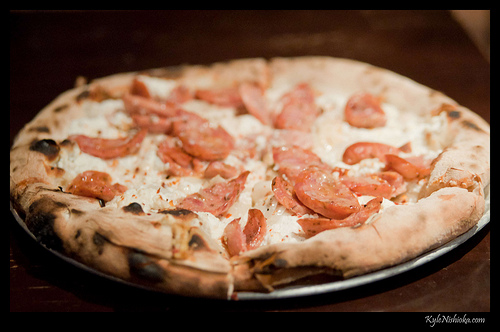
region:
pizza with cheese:
[32, 73, 496, 298]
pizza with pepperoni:
[29, 56, 486, 276]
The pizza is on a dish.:
[16, 60, 471, 297]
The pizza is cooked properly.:
[5, 20, 471, 300]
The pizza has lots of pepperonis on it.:
[25, 55, 476, 301]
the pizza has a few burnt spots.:
[15, 27, 481, 294]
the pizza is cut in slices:
[28, 55, 468, 305]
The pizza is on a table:
[10, 25, 476, 312]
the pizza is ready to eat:
[8, 50, 484, 290]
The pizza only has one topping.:
[15, 42, 402, 317]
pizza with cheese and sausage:
[279, 168, 379, 265]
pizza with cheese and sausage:
[132, 160, 234, 292]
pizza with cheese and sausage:
[20, 124, 153, 238]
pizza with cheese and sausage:
[82, 86, 219, 161]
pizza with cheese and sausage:
[185, 65, 314, 147]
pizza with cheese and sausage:
[289, 62, 413, 172]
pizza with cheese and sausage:
[371, 115, 481, 226]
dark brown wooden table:
[25, 16, 224, 53]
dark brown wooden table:
[244, 11, 471, 54]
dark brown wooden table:
[423, 266, 478, 318]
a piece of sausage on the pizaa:
[281, 156, 379, 224]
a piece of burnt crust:
[127, 235, 172, 306]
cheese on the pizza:
[132, 154, 159, 196]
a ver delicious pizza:
[45, 47, 497, 229]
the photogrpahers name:
[408, 304, 483, 329]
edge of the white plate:
[299, 280, 382, 298]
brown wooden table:
[365, 25, 458, 53]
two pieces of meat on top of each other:
[277, 168, 361, 223]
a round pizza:
[22, 40, 465, 216]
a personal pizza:
[33, 38, 498, 266]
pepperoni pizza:
[30, 51, 478, 288]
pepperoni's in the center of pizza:
[167, 107, 234, 177]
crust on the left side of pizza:
[6, 165, 266, 307]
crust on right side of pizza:
[275, 166, 486, 294]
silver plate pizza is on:
[247, 251, 468, 313]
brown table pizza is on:
[38, 10, 453, 62]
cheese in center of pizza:
[237, 124, 272, 177]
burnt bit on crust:
[112, 252, 166, 288]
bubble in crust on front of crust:
[244, 262, 348, 292]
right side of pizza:
[281, 30, 496, 285]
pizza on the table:
[71, 35, 457, 307]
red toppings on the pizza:
[278, 148, 348, 227]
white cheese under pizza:
[308, 108, 350, 168]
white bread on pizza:
[62, 197, 179, 270]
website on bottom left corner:
[409, 298, 491, 328]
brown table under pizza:
[423, 266, 475, 306]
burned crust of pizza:
[24, 201, 96, 249]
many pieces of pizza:
[93, 48, 420, 261]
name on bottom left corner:
[416, 306, 453, 328]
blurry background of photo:
[217, 14, 387, 99]